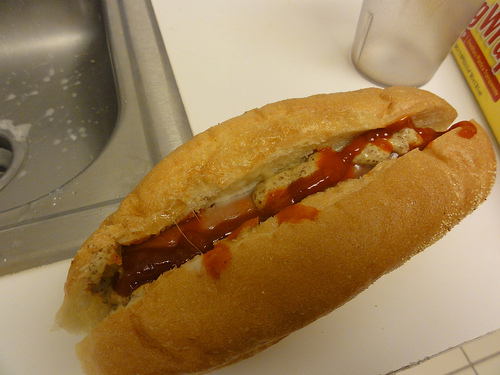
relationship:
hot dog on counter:
[58, 84, 499, 373] [2, 2, 499, 374]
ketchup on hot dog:
[129, 116, 429, 278] [58, 84, 499, 373]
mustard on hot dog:
[186, 150, 385, 199] [58, 84, 499, 373]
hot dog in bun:
[58, 84, 499, 373] [85, 79, 499, 375]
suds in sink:
[1, 52, 99, 165] [0, 2, 182, 279]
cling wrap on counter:
[451, 2, 500, 143] [2, 2, 499, 374]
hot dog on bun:
[58, 84, 499, 373] [85, 79, 499, 375]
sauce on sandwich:
[129, 116, 429, 278] [58, 84, 499, 373]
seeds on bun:
[410, 168, 493, 252] [85, 79, 499, 375]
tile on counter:
[389, 342, 499, 374] [2, 2, 499, 374]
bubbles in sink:
[1, 52, 99, 165] [0, 2, 182, 279]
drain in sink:
[0, 122, 29, 187] [0, 2, 182, 279]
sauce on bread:
[129, 116, 429, 278] [58, 84, 499, 373]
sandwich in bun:
[58, 84, 499, 373] [85, 79, 499, 375]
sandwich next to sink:
[58, 84, 499, 373] [0, 2, 182, 279]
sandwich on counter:
[58, 84, 499, 373] [2, 2, 499, 374]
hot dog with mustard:
[58, 84, 499, 373] [186, 150, 385, 199]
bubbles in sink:
[20, 76, 83, 152] [0, 2, 182, 279]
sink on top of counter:
[0, 2, 182, 279] [2, 2, 499, 374]